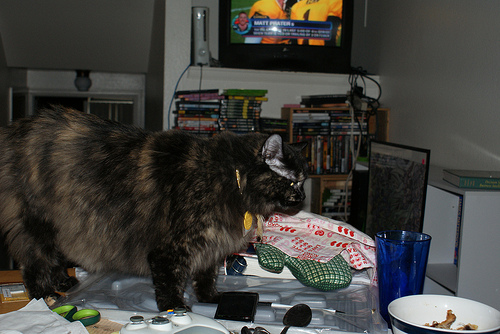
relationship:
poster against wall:
[365, 135, 444, 266] [372, 5, 495, 315]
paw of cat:
[196, 282, 221, 305] [0, 98, 308, 314]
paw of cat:
[170, 295, 200, 315] [0, 98, 308, 314]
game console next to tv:
[192, 4, 212, 63] [216, 0, 354, 75]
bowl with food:
[387, 293, 500, 334] [426, 309, 476, 331]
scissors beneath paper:
[49, 298, 104, 328] [1, 291, 91, 331]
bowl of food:
[387, 293, 497, 333] [425, 311, 475, 330]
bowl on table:
[387, 293, 497, 333] [2, 269, 387, 332]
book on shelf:
[440, 159, 497, 190] [410, 133, 499, 305]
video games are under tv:
[178, 88, 383, 215] [197, 0, 377, 81]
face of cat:
[249, 170, 304, 216] [0, 98, 308, 314]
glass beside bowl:
[364, 218, 415, 316] [375, 269, 495, 332]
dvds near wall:
[169, 79, 392, 180] [378, 24, 480, 123]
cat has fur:
[0, 98, 308, 314] [22, 129, 237, 264]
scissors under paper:
[50, 301, 102, 324] [4, 289, 74, 331]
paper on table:
[4, 289, 74, 331] [34, 254, 475, 328]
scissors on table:
[50, 301, 102, 324] [34, 254, 475, 328]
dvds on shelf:
[220, 87, 268, 98] [176, 103, 396, 215]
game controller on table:
[107, 304, 224, 332] [55, 217, 462, 332]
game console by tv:
[192, 2, 212, 62] [216, 1, 353, 67]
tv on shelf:
[216, 1, 353, 67] [184, 69, 381, 97]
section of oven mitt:
[259, 261, 352, 289] [249, 227, 365, 292]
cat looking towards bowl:
[0, 98, 308, 314] [382, 282, 484, 330]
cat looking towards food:
[0, 98, 308, 314] [414, 306, 482, 332]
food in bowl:
[414, 306, 482, 332] [382, 282, 484, 330]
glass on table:
[371, 230, 429, 329] [31, 236, 468, 330]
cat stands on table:
[0, 98, 308, 314] [342, 299, 364, 332]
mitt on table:
[286, 264, 348, 281] [343, 286, 365, 330]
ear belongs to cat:
[248, 135, 289, 162] [14, 130, 301, 321]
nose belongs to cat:
[281, 184, 299, 204] [21, 100, 311, 320]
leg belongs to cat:
[147, 271, 180, 308] [11, 90, 289, 317]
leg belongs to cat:
[147, 263, 181, 307] [0, 98, 308, 314]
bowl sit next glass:
[387, 293, 500, 334] [376, 235, 424, 295]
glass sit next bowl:
[371, 230, 429, 329] [399, 295, 424, 325]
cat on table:
[16, 104, 304, 308] [329, 302, 352, 330]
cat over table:
[16, 104, 304, 308] [341, 297, 375, 329]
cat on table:
[0, 98, 308, 314] [326, 293, 385, 329]